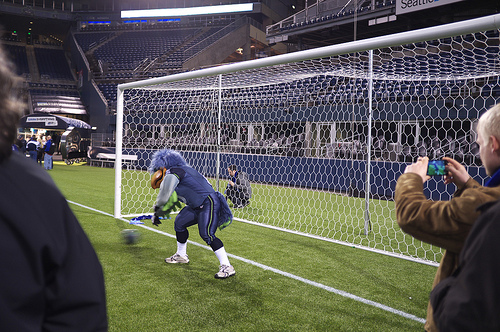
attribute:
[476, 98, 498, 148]
hair — blonde, man's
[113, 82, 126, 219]
pole — fence, white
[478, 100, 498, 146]
hair — short, man's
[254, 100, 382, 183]
mesh — white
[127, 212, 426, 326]
line — white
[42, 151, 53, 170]
jeans — blue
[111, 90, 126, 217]
fence pole — metal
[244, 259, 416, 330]
stripe — white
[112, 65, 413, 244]
bars — white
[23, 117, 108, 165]
seats — blue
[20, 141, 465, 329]
grass — green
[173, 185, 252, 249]
pants — blue and gold